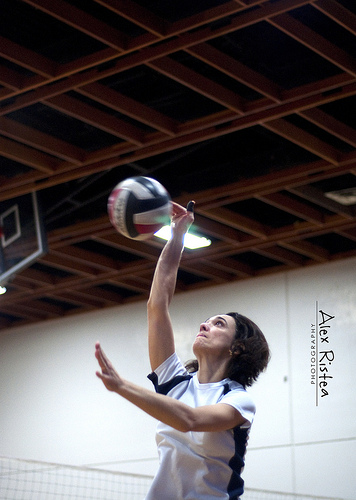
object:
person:
[89, 193, 275, 499]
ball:
[98, 168, 180, 247]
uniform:
[124, 353, 262, 499]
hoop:
[0, 177, 69, 284]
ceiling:
[1, 0, 355, 303]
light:
[150, 213, 218, 258]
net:
[1, 452, 355, 498]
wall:
[2, 247, 355, 496]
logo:
[305, 295, 340, 413]